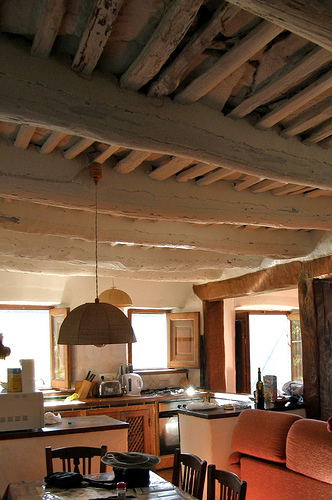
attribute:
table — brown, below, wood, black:
[67, 462, 170, 500]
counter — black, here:
[183, 399, 231, 424]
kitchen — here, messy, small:
[8, 307, 294, 423]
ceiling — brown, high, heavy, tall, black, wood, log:
[0, 0, 330, 221]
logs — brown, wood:
[2, 3, 330, 244]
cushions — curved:
[227, 403, 330, 489]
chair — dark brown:
[163, 446, 206, 493]